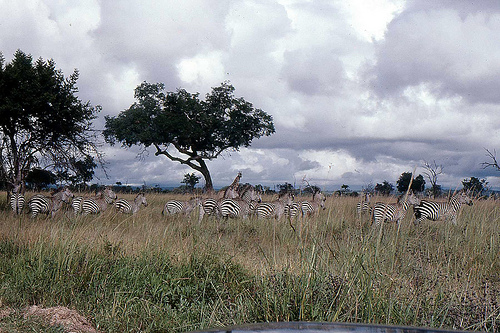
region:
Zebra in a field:
[413, 184, 486, 229]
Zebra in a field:
[373, 184, 409, 244]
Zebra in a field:
[342, 183, 378, 239]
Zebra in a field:
[290, 181, 344, 231]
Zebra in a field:
[255, 187, 295, 237]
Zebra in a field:
[218, 184, 270, 244]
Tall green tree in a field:
[120, 65, 265, 185]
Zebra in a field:
[113, 181, 147, 228]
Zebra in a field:
[86, 186, 121, 227]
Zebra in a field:
[35, 186, 75, 235]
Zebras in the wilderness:
[53, 173, 478, 242]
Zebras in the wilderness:
[353, 184, 478, 241]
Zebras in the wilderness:
[58, 180, 146, 220]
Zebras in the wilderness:
[166, 176, 275, 232]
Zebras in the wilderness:
[18, 178, 110, 225]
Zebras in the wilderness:
[242, 181, 327, 235]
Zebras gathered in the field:
[122, 159, 374, 266]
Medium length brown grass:
[187, 215, 364, 320]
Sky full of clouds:
[265, 40, 430, 146]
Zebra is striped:
[94, 183, 151, 217]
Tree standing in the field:
[92, 71, 290, 200]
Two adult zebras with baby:
[336, 175, 496, 247]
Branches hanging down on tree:
[31, 84, 163, 232]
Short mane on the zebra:
[130, 182, 145, 200]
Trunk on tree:
[182, 151, 215, 197]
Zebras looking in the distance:
[185, 148, 492, 259]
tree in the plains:
[108, 77, 274, 201]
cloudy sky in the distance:
[273, 12, 448, 129]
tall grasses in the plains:
[146, 235, 478, 307]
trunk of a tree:
[168, 151, 218, 186]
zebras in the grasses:
[33, 177, 488, 259]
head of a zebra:
[451, 186, 474, 212]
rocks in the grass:
[16, 297, 98, 332]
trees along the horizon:
[108, 168, 329, 194]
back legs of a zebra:
[213, 216, 228, 239]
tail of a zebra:
[23, 196, 34, 220]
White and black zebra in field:
[413, 186, 486, 241]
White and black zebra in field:
[372, 184, 427, 247]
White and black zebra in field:
[353, 181, 380, 228]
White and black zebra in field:
[284, 186, 342, 238]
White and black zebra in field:
[259, 179, 286, 234]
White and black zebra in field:
[218, 181, 268, 248]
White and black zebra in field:
[193, 184, 242, 241]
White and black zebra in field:
[160, 183, 212, 238]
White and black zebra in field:
[113, 186, 158, 228]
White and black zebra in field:
[68, 179, 132, 231]